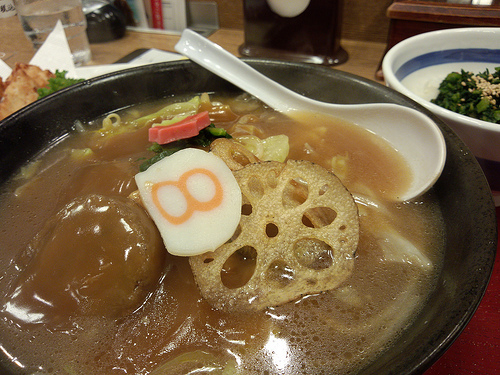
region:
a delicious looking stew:
[16, 158, 423, 361]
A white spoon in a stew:
[179, 16, 450, 169]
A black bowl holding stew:
[5, 43, 471, 373]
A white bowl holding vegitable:
[385, 21, 497, 112]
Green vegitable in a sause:
[448, 61, 498, 106]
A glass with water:
[16, 4, 103, 65]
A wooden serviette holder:
[236, 2, 351, 67]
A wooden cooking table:
[3, 13, 498, 371]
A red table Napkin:
[448, 326, 498, 371]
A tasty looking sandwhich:
[2, 60, 64, 103]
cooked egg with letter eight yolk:
[130, 141, 250, 278]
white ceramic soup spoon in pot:
[173, 21, 459, 206]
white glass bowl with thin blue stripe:
[379, 24, 499, 164]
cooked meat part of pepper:
[181, 161, 370, 313]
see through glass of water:
[10, 1, 112, 71]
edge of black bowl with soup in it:
[337, 71, 495, 339]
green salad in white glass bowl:
[428, 50, 498, 124]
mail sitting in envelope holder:
[120, 0, 224, 41]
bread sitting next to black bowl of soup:
[1, 51, 142, 171]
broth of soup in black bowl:
[298, 266, 423, 368]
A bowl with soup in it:
[5, 57, 483, 368]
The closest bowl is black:
[0, 63, 492, 367]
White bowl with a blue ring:
[380, 2, 497, 174]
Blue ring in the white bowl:
[391, 38, 498, 83]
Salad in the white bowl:
[421, 42, 497, 132]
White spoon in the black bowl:
[156, 10, 467, 218]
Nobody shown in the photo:
[15, 2, 493, 363]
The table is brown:
[1, 31, 390, 109]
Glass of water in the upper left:
[17, 5, 104, 66]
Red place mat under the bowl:
[447, 134, 494, 374]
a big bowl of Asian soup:
[5, 0, 498, 355]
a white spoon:
[169, 26, 454, 213]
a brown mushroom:
[179, 155, 374, 326]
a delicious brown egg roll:
[3, 57, 56, 127]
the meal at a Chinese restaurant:
[2, 1, 492, 373]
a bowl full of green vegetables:
[383, 15, 495, 162]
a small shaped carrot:
[141, 115, 221, 145]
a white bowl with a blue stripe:
[369, 11, 497, 178]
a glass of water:
[4, 0, 98, 64]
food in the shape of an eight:
[128, 151, 245, 270]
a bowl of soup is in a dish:
[6, 58, 498, 369]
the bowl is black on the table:
[6, 54, 493, 374]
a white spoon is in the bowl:
[175, 25, 449, 211]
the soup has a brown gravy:
[18, 125, 416, 357]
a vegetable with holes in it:
[201, 156, 356, 303]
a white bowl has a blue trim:
[383, 22, 499, 164]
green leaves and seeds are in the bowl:
[431, 60, 496, 121]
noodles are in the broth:
[319, 281, 422, 358]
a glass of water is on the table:
[14, 1, 101, 67]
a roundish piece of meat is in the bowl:
[8, 195, 158, 332]